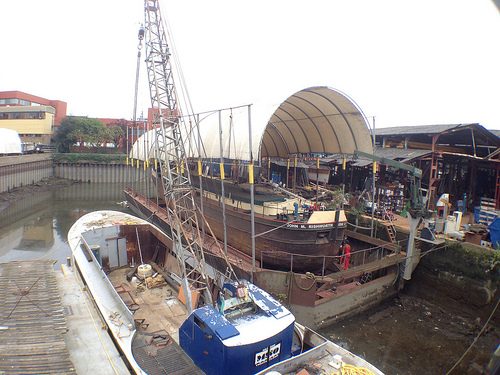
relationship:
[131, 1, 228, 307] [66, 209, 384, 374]
crane attached to a boat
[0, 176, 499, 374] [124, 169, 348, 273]
water below boat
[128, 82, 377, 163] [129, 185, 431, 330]
tent covering dock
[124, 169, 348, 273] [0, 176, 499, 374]
boat docked on water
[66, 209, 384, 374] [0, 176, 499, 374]
boat docked on water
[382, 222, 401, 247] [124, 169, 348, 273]
ladder next to boat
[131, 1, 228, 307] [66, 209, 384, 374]
crane on a boat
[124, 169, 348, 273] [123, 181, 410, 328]
boat on top of a container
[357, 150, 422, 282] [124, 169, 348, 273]
lift on back of a boat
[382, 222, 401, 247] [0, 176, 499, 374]
ladder leading to water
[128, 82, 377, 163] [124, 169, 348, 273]
tent above boat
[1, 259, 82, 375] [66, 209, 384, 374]
pier beside boat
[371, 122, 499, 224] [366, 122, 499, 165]
shelter has a roof